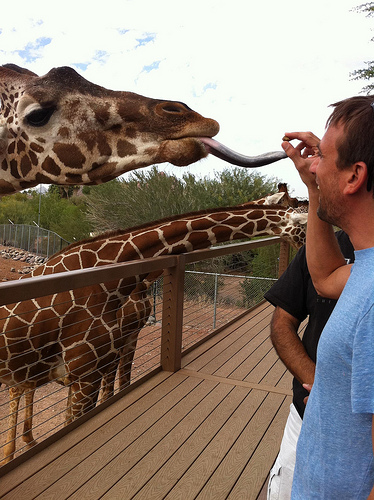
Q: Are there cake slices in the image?
A: No, there are no cake slices.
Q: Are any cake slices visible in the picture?
A: No, there are no cake slices.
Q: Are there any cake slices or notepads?
A: No, there are no cake slices or notepads.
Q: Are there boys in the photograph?
A: No, there are no boys.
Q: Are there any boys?
A: No, there are no boys.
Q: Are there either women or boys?
A: No, there are no boys or women.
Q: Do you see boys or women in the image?
A: No, there are no boys or women.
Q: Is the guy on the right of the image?
A: Yes, the guy is on the right of the image.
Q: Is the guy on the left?
A: No, the guy is on the right of the image.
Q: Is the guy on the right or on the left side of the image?
A: The guy is on the right of the image.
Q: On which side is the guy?
A: The guy is on the right of the image.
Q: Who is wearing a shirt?
A: The guy is wearing a shirt.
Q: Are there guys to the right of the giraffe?
A: Yes, there is a guy to the right of the giraffe.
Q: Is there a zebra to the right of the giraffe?
A: No, there is a guy to the right of the giraffe.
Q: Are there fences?
A: Yes, there is a fence.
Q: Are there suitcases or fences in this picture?
A: Yes, there is a fence.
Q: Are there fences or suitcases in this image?
A: Yes, there is a fence.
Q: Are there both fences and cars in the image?
A: No, there is a fence but no cars.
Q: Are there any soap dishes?
A: No, there are no soap dishes.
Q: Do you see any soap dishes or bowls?
A: No, there are no soap dishes or bowls.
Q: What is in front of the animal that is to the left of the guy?
A: The fence is in front of the giraffe.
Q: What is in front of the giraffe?
A: The fence is in front of the giraffe.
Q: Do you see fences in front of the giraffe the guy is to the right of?
A: Yes, there is a fence in front of the giraffe.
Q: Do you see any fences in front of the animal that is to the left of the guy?
A: Yes, there is a fence in front of the giraffe.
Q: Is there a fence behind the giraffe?
A: No, the fence is in front of the giraffe.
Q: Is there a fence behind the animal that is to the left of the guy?
A: No, the fence is in front of the giraffe.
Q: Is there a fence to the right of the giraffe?
A: Yes, there is a fence to the right of the giraffe.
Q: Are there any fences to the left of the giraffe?
A: No, the fence is to the right of the giraffe.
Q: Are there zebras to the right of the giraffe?
A: No, there is a fence to the right of the giraffe.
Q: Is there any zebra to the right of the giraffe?
A: No, there is a fence to the right of the giraffe.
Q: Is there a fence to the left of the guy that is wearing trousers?
A: Yes, there is a fence to the left of the guy.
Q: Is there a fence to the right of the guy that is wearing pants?
A: No, the fence is to the left of the guy.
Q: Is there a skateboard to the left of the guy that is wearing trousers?
A: No, there is a fence to the left of the guy.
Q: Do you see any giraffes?
A: Yes, there is a giraffe.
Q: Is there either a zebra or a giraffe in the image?
A: Yes, there is a giraffe.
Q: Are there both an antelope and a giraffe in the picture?
A: No, there is a giraffe but no antelopes.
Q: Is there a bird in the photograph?
A: No, there are no birds.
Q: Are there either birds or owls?
A: No, there are no birds or owls.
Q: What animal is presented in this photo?
A: The animal is a giraffe.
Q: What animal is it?
A: The animal is a giraffe.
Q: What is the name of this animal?
A: This is a giraffe.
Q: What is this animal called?
A: This is a giraffe.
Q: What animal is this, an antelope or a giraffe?
A: This is a giraffe.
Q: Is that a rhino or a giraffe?
A: That is a giraffe.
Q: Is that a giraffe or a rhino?
A: That is a giraffe.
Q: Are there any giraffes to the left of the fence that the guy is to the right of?
A: Yes, there is a giraffe to the left of the fence.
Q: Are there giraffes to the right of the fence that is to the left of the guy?
A: No, the giraffe is to the left of the fence.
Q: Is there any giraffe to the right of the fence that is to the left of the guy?
A: No, the giraffe is to the left of the fence.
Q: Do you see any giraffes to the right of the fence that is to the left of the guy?
A: No, the giraffe is to the left of the fence.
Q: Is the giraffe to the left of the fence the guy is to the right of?
A: Yes, the giraffe is to the left of the fence.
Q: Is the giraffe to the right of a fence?
A: No, the giraffe is to the left of a fence.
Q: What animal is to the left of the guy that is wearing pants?
A: The animal is a giraffe.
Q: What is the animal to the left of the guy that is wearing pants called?
A: The animal is a giraffe.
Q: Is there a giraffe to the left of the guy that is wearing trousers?
A: Yes, there is a giraffe to the left of the guy.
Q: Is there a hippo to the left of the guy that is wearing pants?
A: No, there is a giraffe to the left of the guy.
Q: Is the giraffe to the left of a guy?
A: Yes, the giraffe is to the left of a guy.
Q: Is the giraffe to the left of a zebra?
A: No, the giraffe is to the left of a guy.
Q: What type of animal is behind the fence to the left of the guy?
A: The animal is a giraffe.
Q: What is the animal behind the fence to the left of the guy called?
A: The animal is a giraffe.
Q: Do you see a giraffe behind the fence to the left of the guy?
A: Yes, there is a giraffe behind the fence.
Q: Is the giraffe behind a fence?
A: Yes, the giraffe is behind a fence.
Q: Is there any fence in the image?
A: Yes, there is a fence.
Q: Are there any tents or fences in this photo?
A: Yes, there is a fence.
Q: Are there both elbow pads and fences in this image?
A: No, there is a fence but no elbow pads.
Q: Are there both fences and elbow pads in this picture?
A: No, there is a fence but no elbow pads.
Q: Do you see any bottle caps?
A: No, there are no bottle caps.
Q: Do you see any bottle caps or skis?
A: No, there are no bottle caps or skis.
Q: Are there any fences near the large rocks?
A: Yes, there is a fence near the rocks.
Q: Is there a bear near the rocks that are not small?
A: No, there is a fence near the rocks.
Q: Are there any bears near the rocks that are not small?
A: No, there is a fence near the rocks.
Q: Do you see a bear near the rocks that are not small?
A: No, there is a fence near the rocks.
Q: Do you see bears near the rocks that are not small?
A: No, there is a fence near the rocks.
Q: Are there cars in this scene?
A: No, there are no cars.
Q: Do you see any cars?
A: No, there are no cars.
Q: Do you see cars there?
A: No, there are no cars.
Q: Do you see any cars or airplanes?
A: No, there are no cars or airplanes.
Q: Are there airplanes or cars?
A: No, there are no cars or airplanes.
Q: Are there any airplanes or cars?
A: No, there are no cars or airplanes.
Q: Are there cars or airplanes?
A: No, there are no cars or airplanes.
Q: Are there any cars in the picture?
A: No, there are no cars.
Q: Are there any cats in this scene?
A: No, there are no cats.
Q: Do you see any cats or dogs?
A: No, there are no cats or dogs.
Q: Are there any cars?
A: No, there are no cars.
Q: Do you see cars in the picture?
A: No, there are no cars.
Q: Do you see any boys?
A: No, there are no boys.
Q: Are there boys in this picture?
A: No, there are no boys.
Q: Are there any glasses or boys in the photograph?
A: No, there are no boys or glasses.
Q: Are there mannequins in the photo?
A: No, there are no mannequins.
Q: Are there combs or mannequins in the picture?
A: No, there are no mannequins or combs.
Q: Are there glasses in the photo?
A: No, there are no glasses.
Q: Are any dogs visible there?
A: No, there are no dogs.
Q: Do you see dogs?
A: No, there are no dogs.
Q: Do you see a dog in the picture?
A: No, there are no dogs.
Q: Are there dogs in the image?
A: No, there are no dogs.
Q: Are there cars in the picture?
A: No, there are no cars.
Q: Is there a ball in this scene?
A: No, there are no balls.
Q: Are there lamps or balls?
A: No, there are no balls or lamps.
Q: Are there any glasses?
A: No, there are no glasses.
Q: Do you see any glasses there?
A: No, there are no glasses.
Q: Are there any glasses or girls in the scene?
A: No, there are no glasses or girls.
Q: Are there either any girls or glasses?
A: No, there are no glasses or girls.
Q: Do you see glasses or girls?
A: No, there are no glasses or girls.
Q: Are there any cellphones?
A: No, there are no cellphones.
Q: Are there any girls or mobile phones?
A: No, there are no mobile phones or girls.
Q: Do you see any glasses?
A: No, there are no glasses.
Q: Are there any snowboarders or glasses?
A: No, there are no glasses or snowboarders.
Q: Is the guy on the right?
A: Yes, the guy is on the right of the image.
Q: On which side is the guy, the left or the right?
A: The guy is on the right of the image.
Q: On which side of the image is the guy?
A: The guy is on the right of the image.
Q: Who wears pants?
A: The guy wears pants.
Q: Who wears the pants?
A: The guy wears pants.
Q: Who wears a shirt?
A: The guy wears a shirt.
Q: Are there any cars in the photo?
A: No, there are no cars.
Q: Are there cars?
A: No, there are no cars.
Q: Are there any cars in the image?
A: No, there are no cars.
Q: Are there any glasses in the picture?
A: No, there are no glasses.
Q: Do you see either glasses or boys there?
A: No, there are no glasses or boys.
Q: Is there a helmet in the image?
A: No, there are no helmets.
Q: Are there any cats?
A: No, there are no cats.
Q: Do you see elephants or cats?
A: No, there are no cats or elephants.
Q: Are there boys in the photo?
A: No, there are no boys.